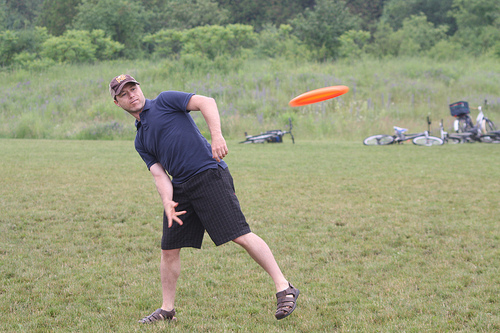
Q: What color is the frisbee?
A: Orange.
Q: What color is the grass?
A: Green.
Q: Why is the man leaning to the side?
A: He is preparing to catch the frisbee.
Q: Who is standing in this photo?
A: A man.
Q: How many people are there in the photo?
A: One.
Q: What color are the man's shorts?
A: Black.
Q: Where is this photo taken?
A: On a field.